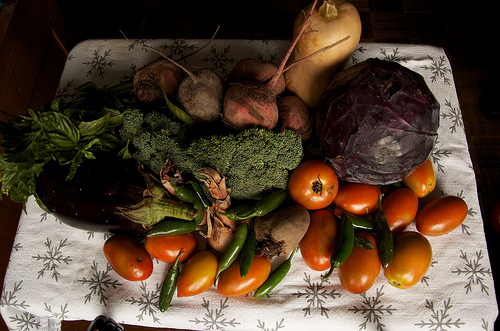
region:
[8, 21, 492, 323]
The table cloth is white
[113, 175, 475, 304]
Red and green vegetables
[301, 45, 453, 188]
Round and purple vegetable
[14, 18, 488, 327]
The table cloth has silver snowflakes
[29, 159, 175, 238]
The bowl is black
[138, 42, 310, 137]
The vegetables are brown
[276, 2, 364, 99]
Tall beige squash on the table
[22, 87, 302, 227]
Green leafy plants on the pile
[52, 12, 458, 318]
A pile of vegetables on the cloth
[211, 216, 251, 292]
Long and thin green vegetable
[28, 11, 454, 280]
vegetables on a cloth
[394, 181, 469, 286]
red tomatoes on a cloth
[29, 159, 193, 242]
purple eggplant on a cloth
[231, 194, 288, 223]
green pepper on a beet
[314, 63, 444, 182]
purple cabbage on a cloth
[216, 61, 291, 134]
beets on a cloth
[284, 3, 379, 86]
squash on a cloth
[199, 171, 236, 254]
onion on a cloth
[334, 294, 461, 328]
cloth with snow flakes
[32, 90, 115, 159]
green herb on a cloth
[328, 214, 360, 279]
Green pepper on plate.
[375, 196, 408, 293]
Green pepper on plate.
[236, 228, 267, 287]
Green pepper on plate.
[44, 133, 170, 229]
Purple egg plant on plate.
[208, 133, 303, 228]
Green broccoli on plate.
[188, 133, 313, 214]
the vegetable is green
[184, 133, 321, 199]
vegetable is a broccoli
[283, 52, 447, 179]
purple vegetable on mat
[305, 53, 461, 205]
vegetable is a cabagge head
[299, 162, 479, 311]
red vegetable on mat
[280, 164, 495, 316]
vegetable is a tomato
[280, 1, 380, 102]
orange vegetable on mat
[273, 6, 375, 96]
vegetable is squash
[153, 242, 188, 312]
green vegetable on mat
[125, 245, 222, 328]
green vegetable is a pepper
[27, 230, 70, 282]
gray snowglake design on a white cloth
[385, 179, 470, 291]
tomatoes on a white cloth with gray designs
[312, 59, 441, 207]
head of red cabbage with tomatoes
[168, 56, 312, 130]
red beet roots with dirt on them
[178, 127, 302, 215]
green broccoli crown with green pepper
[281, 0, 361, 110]
light orange butternut squash with stem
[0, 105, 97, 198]
green leafy vegatables in a black bowl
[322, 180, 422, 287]
green peppers and red tomatoes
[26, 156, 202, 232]
black eggplant with green stem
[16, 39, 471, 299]
mixed vegatables on a table with white cloth